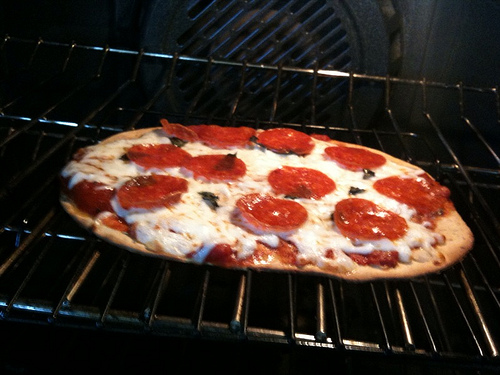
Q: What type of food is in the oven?
A: Pizza.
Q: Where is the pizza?
A: In the oven.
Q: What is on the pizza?
A: Cheese and pepperoni.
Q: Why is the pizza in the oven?
A: To cook.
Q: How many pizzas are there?
A: One.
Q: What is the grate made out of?
A: Metal.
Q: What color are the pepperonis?
A: Red.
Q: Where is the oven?
A: In the kitchen.